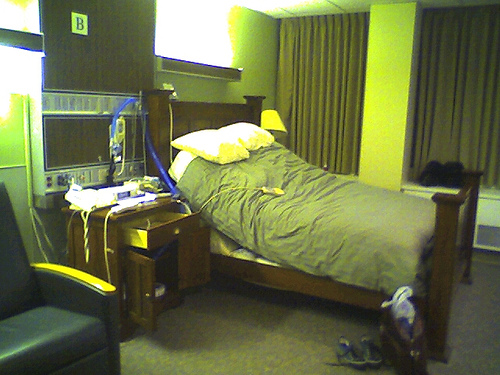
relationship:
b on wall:
[71, 13, 86, 36] [31, 1, 159, 188]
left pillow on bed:
[224, 119, 282, 154] [142, 86, 484, 367]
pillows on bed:
[171, 129, 248, 165] [142, 86, 484, 367]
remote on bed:
[186, 185, 286, 206] [142, 86, 484, 367]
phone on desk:
[69, 184, 113, 267] [63, 180, 215, 342]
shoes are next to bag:
[331, 330, 384, 373] [381, 283, 430, 374]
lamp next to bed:
[0, 3, 47, 172] [142, 86, 484, 367]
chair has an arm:
[2, 175, 121, 374] [30, 258, 120, 304]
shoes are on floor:
[331, 330, 384, 373] [110, 246, 499, 374]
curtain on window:
[266, 16, 499, 193] [275, 14, 499, 187]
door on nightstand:
[121, 247, 162, 333] [63, 180, 215, 342]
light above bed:
[152, 0, 238, 69] [142, 86, 484, 367]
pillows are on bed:
[171, 124, 276, 165] [142, 86, 484, 367]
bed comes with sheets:
[142, 86, 484, 367] [172, 133, 444, 295]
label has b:
[67, 5, 92, 37] [71, 13, 86, 36]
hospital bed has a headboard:
[142, 86, 484, 367] [140, 75, 265, 188]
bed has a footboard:
[142, 86, 484, 367] [412, 166, 481, 365]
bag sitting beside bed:
[381, 283, 430, 374] [142, 86, 484, 367]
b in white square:
[71, 13, 86, 36] [67, 5, 92, 37]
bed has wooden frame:
[142, 86, 484, 367] [140, 75, 265, 188]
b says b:
[71, 13, 86, 36] [71, 13, 86, 36]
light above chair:
[152, 0, 238, 69] [2, 175, 121, 374]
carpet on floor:
[110, 246, 499, 374] [109, 234, 485, 365]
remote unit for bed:
[254, 185, 288, 198] [143, 74, 479, 341]